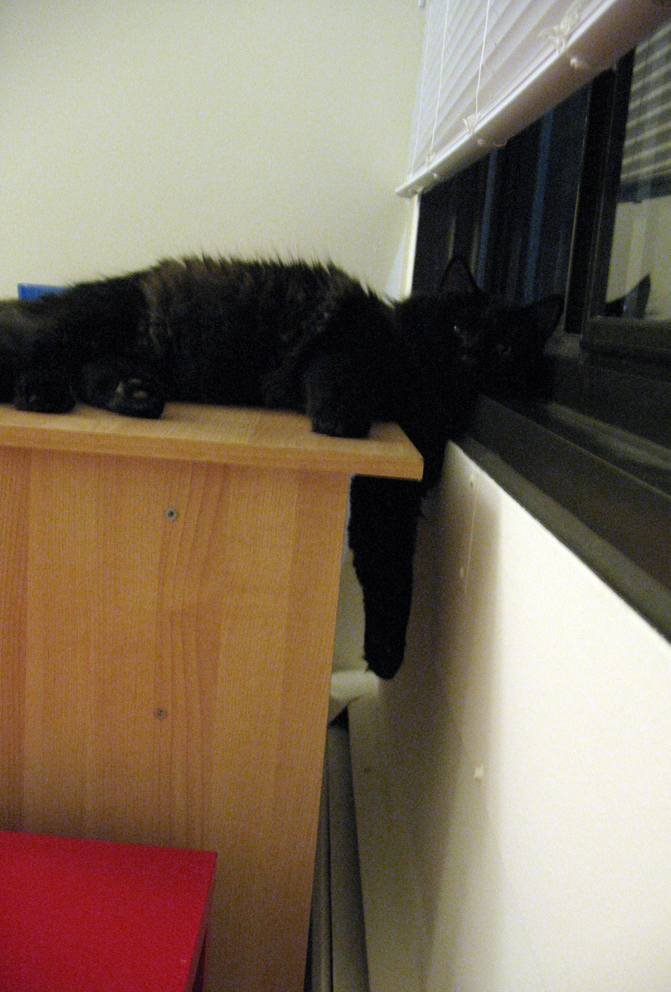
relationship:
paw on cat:
[304, 396, 375, 443] [0, 250, 567, 699]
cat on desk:
[0, 250, 567, 699] [0, 400, 425, 992]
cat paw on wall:
[349, 476, 415, 677] [415, 519, 485, 715]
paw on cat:
[12, 353, 97, 431] [26, 191, 598, 480]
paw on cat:
[110, 370, 169, 418] [26, 191, 598, 480]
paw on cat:
[360, 637, 408, 684] [26, 191, 598, 480]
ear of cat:
[525, 291, 565, 344] [0, 250, 567, 699]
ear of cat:
[438, 252, 479, 298] [0, 250, 567, 699]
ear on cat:
[525, 286, 568, 354] [411, 254, 572, 351]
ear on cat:
[438, 252, 479, 298] [411, 254, 572, 351]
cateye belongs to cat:
[453, 327, 458, 333] [1, 242, 501, 682]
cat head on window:
[381, 247, 574, 417] [384, 0, 669, 639]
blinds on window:
[393, 2, 670, 198] [424, 16, 670, 483]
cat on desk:
[0, 250, 567, 699] [44, 400, 385, 494]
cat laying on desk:
[0, 250, 567, 699] [1, 374, 425, 986]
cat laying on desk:
[1, 242, 501, 682] [1, 374, 425, 986]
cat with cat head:
[0, 250, 567, 699] [428, 247, 566, 409]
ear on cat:
[438, 252, 483, 298] [2, 248, 563, 445]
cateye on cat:
[453, 326, 468, 341] [0, 250, 567, 699]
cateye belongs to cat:
[453, 327, 458, 333] [0, 250, 567, 699]